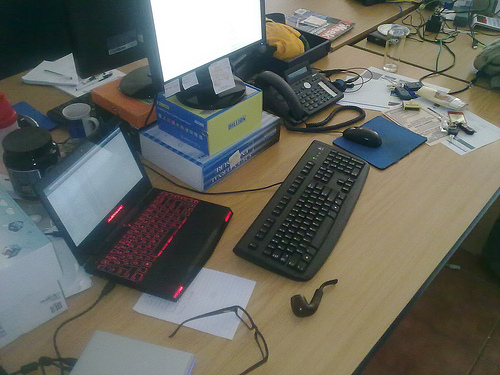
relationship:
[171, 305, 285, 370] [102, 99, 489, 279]
glasses on desk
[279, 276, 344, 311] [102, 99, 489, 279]
pipe on desk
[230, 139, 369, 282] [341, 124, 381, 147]
keyboard by mouse